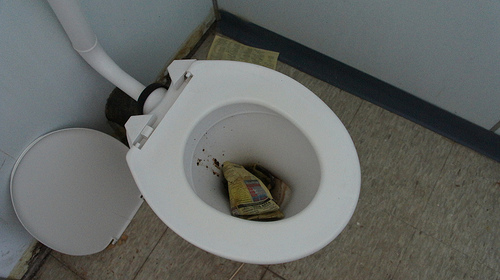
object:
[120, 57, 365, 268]
toilet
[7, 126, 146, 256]
seat cover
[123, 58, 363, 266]
seat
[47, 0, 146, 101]
pipe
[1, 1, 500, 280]
room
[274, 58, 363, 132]
tiling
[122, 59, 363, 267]
bowl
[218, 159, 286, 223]
trash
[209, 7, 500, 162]
base board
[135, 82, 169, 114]
connector ring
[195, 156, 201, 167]
stain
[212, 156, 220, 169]
stain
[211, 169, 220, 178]
stain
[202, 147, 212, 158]
stain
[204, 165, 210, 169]
stain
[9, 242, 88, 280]
damage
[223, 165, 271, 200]
drain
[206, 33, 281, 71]
paper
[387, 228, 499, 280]
tile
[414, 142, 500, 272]
tile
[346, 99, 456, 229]
tile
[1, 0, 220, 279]
wall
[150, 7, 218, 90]
missing baseboard